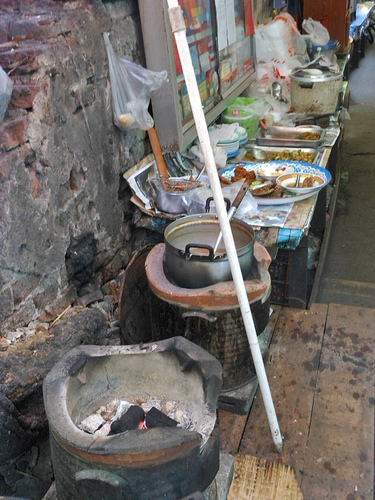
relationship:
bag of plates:
[257, 16, 293, 65] [257, 16, 301, 77]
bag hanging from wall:
[102, 34, 169, 130] [31, 9, 139, 165]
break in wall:
[55, 225, 110, 304] [2, 0, 110, 338]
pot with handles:
[158, 212, 261, 285] [203, 195, 228, 212]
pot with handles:
[158, 212, 261, 285] [180, 239, 214, 258]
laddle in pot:
[209, 172, 252, 254] [160, 211, 254, 282]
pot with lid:
[295, 70, 341, 113] [293, 61, 339, 81]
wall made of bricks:
[2, 72, 148, 498] [5, 186, 90, 281]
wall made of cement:
[2, 72, 148, 498] [0, 181, 107, 367]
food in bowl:
[237, 164, 315, 194] [231, 160, 327, 198]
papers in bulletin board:
[208, 3, 246, 48] [139, 1, 257, 153]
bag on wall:
[69, 26, 183, 162] [19, 19, 142, 294]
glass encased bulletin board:
[202, 33, 238, 80] [164, 4, 269, 119]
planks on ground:
[210, 293, 372, 498] [264, 305, 361, 459]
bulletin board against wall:
[139, 1, 257, 153] [0, 3, 147, 318]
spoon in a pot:
[208, 169, 255, 254] [162, 210, 256, 290]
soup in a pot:
[185, 248, 233, 253] [162, 210, 256, 290]